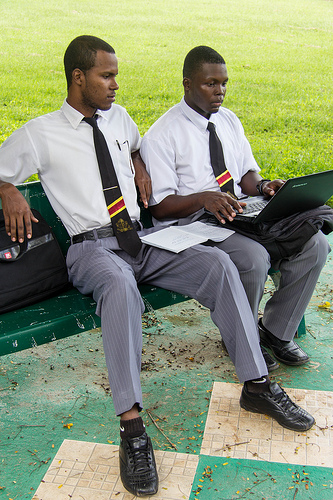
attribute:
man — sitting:
[139, 45, 331, 372]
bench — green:
[1, 180, 195, 356]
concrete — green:
[0, 232, 331, 499]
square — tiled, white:
[30, 439, 201, 499]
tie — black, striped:
[81, 114, 143, 260]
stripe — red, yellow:
[106, 195, 127, 218]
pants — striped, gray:
[208, 231, 330, 343]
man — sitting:
[0, 35, 315, 499]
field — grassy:
[1, 1, 332, 206]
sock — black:
[118, 416, 146, 441]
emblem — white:
[118, 426, 126, 432]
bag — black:
[0, 208, 69, 315]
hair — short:
[182, 45, 225, 76]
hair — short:
[63, 34, 116, 88]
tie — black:
[207, 122, 238, 200]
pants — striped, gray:
[64, 221, 269, 416]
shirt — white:
[138, 97, 261, 227]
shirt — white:
[0, 97, 143, 237]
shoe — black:
[239, 380, 318, 433]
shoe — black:
[118, 429, 160, 497]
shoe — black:
[220, 338, 281, 371]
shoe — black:
[256, 316, 311, 367]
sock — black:
[243, 376, 273, 394]